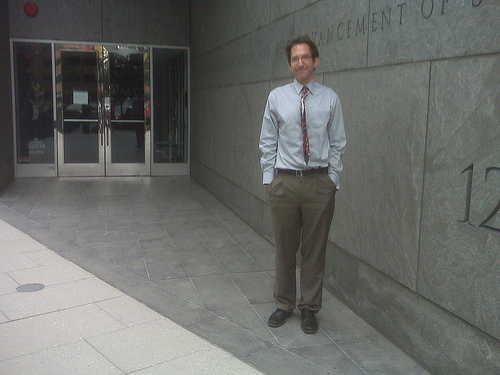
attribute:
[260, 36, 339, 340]
man — smiling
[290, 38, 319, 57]
hair — short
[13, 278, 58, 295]
grate — round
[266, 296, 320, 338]
shoes — black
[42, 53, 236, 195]
doors — glass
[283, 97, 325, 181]
tie — silver, red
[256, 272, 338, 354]
shoes — black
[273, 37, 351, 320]
man — standing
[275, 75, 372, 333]
man — standing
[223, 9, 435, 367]
man — smiling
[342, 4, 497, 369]
building — granite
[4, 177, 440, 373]
flooring — concrete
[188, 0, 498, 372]
wall — concrete